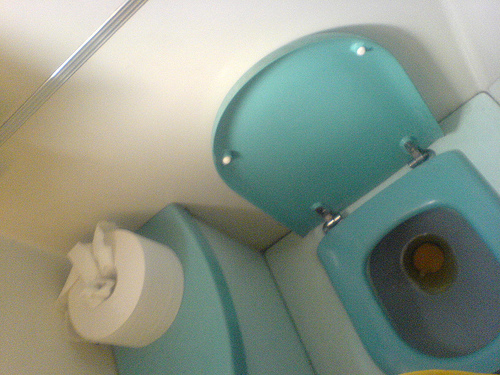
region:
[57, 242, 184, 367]
Toilet roll on seat.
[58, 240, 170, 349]
Toilet paper is white.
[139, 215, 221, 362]
Toilet seat is blue.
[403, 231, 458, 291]
Water in the toilet.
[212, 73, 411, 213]
Toilet lid is up.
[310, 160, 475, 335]
The toilet is blue.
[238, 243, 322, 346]
The floor is white.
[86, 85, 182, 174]
The wall is beige.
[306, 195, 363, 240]
Hooks on the toilet.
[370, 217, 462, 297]
Something in the toilet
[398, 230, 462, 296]
inside of toilet is unflushed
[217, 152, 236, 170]
white bumper pad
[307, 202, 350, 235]
silver toilet lid hinge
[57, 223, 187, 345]
toilet paper roll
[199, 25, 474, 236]
aqua colored toilet seat lid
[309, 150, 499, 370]
aqua colored toilet seat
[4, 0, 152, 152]
silver trim on wall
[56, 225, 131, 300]
toilet paper tucked inside toilet paper roll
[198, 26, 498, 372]
toilet with lid open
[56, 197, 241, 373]
toilet paper sitting on ledge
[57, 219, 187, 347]
Roll of white toilet paper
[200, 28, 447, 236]
Aqua toilet lid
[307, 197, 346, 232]
Silver hinge on toilet lid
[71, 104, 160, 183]
Cream colored bathroom wall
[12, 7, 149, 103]
Silver trim on bathroom wall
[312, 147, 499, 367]
Aqua toilet seat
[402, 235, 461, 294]
Dirt inside toilet bowl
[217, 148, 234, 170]
White piece on toilet lid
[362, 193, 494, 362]
Dirty toilet bowl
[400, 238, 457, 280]
Drain hole in toilet bowl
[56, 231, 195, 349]
A large roll of toilet paper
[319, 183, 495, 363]
The toilet bowl has urine in it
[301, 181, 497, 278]
The toilet bowl's rim is blue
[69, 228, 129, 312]
Toilet paper inside the roll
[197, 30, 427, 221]
The toilet's lid is blue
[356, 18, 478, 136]
The lid's shadow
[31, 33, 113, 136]
A rack against the wall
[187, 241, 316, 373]
The lid of the container is blue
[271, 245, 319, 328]
The floor is light blue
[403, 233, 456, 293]
The liquid is yellow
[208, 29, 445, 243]
lid of plastic toilet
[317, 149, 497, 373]
blue, plastic toilet seat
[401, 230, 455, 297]
urine visible in toilet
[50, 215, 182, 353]
a large roll of toilet paper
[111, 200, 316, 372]
shelf under the toilet paper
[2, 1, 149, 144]
a metal bar on the wall above the toilet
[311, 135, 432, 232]
metal hinge on the toilet seat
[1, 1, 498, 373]
white walls of the bathroom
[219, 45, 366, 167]
white supports on the toilet lid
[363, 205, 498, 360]
inside of toilet bowl